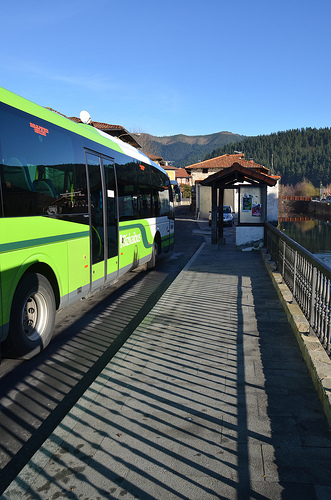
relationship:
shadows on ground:
[124, 271, 236, 390] [75, 279, 227, 486]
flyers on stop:
[236, 185, 295, 243] [181, 170, 294, 269]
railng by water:
[254, 228, 327, 294] [287, 217, 322, 240]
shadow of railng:
[198, 348, 256, 446] [263, 221, 331, 360]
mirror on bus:
[170, 178, 199, 203] [21, 123, 156, 267]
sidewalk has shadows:
[124, 264, 252, 434] [124, 271, 236, 390]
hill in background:
[131, 124, 330, 196] [138, 108, 327, 183]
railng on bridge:
[263, 221, 331, 360] [209, 195, 331, 433]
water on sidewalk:
[287, 217, 322, 240] [124, 264, 252, 434]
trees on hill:
[249, 123, 314, 173] [233, 138, 321, 184]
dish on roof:
[65, 90, 129, 136] [174, 142, 280, 193]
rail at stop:
[272, 220, 312, 261] [181, 170, 294, 269]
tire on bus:
[3, 272, 90, 351] [21, 123, 156, 267]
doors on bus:
[77, 123, 132, 275] [21, 123, 156, 267]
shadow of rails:
[198, 348, 256, 446] [250, 249, 330, 317]